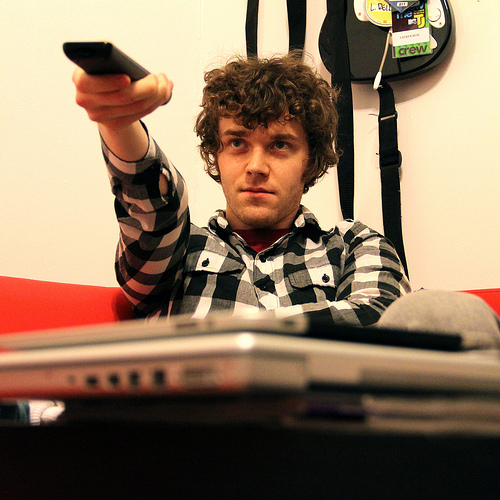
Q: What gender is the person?
A: Male.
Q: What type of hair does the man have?
A: Curly.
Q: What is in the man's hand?
A: Remote control.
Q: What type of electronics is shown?
A: Laptop.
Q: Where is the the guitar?
A: Hanging on the wall.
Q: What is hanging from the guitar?
A: A black strap.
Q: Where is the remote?
A: Man's right hand.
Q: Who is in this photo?
A: A man in a plaid shirt.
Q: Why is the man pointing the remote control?
A: To change the channel.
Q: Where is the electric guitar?
A: Hanging on the wall.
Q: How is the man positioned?
A: Sitting on a couch.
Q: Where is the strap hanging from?
A: The electric guitar.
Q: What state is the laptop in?
A: Closed.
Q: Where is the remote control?
A: In the man's hand.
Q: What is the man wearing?
A: A plaid shirt.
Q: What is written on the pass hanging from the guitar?
A: Crew.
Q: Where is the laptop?
A: In front of the man.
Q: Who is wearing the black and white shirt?
A: The man.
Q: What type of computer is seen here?
A: Gray laptop.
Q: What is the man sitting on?
A: Bright orange sofa.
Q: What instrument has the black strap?
A: A guitar.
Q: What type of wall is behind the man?
A: Off white wall.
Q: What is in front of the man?
A: Gray laptop.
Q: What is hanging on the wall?
A: A guitar.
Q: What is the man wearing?
A: Black and white flannel shirt.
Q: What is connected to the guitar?
A: The strap.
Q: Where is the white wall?
A: Behind the couch.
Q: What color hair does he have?
A: Brown.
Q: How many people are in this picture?
A: One.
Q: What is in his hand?
A: Remote.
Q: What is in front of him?
A: A laptop.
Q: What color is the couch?
A: Red.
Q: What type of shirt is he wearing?
A: Flannel.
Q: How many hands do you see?
A: One.